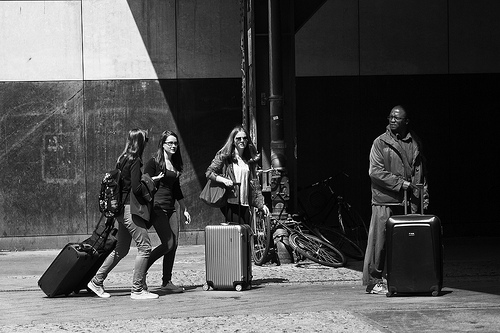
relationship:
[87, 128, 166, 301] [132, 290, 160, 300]
woman wearing shoe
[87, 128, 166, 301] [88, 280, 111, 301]
woman wearing shoe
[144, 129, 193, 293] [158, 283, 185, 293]
woman wearing shoe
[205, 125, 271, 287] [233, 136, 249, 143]
woman wearing sunglasses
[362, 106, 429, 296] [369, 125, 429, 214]
man wearing jacket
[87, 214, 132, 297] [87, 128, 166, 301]
leg of a woman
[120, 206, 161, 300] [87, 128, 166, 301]
leg of a woman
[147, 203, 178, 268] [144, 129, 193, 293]
leg of a woman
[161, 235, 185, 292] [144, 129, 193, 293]
leg of a woman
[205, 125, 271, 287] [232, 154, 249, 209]
woman wearing shirt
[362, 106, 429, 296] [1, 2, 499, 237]
person in front of building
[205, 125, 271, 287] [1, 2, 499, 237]
person in front of building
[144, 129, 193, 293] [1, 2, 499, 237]
person in front of building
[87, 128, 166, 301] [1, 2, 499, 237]
person in front of building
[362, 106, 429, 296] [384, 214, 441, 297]
person with suitcase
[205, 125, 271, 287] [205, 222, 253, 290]
person with suitcase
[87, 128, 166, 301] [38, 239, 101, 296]
person with suitcase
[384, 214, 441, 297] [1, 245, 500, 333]
luggage on ground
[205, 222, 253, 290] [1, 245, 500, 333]
luggage on ground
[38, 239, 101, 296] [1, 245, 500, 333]
luggage on ground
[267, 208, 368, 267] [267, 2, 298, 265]
bicycle by pole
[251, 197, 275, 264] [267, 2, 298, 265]
bike by pole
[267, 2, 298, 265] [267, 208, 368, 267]
pole by bicycle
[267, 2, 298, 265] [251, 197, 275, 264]
pole by bike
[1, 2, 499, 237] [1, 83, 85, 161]
wall has crack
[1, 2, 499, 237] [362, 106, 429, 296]
wall behind person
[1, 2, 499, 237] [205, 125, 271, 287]
wall behind person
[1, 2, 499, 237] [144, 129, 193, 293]
wall behind person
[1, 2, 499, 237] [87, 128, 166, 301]
wall behind person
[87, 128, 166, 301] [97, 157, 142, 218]
woman has backpack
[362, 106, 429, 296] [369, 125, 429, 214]
man with a jacket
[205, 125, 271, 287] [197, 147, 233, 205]
woman has a purse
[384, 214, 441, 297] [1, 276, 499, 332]
suitcase on sidewalk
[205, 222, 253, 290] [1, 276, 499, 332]
suitcase on sidewalk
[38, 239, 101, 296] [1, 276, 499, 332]
suitcase on sidewalk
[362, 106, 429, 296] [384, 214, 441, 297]
person with a suitcase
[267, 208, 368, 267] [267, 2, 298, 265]
bicycle against post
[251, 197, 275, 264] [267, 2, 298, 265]
bicycle against post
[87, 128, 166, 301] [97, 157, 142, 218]
woman wearing backpack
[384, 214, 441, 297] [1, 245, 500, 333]
suitcase on ground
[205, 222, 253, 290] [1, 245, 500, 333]
suitcase on ground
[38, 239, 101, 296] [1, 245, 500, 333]
suitcase on ground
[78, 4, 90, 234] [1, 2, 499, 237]
line on wall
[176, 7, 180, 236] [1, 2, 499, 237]
line on wall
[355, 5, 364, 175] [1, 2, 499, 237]
line on wall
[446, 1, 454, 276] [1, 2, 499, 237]
line on wall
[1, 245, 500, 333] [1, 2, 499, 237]
ground in front of building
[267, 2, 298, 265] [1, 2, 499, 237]
pole by building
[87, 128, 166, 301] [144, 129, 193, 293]
woman by a woman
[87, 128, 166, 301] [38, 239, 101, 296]
woman carrying luggage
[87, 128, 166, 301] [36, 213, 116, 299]
woman pulling luggage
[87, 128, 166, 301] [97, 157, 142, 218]
woman has a bag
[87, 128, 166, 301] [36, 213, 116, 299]
woman carrying luggage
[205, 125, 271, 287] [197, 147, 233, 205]
woman wearing bag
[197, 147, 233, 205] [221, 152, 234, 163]
bag on shoulder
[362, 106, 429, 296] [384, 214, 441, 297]
man holding luggage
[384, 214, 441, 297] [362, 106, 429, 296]
luggage by man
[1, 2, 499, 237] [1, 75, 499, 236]
wall has black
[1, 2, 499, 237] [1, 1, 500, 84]
wall has white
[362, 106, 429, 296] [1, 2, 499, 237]
person by building